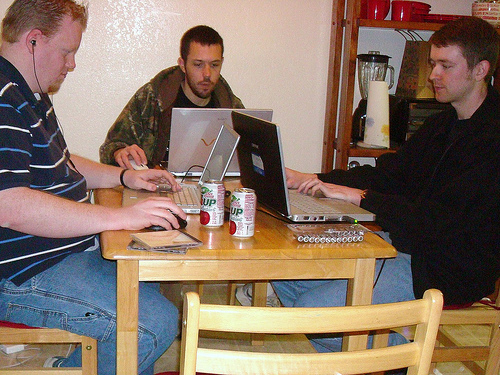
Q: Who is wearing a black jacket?
A: Man on the right.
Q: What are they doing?
A: Looking at their computers.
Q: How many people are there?
A: Three.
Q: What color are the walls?
A: White.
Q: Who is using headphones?
A: The man on the left.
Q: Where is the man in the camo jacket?
A: In the middle.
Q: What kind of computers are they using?
A: Laptops.